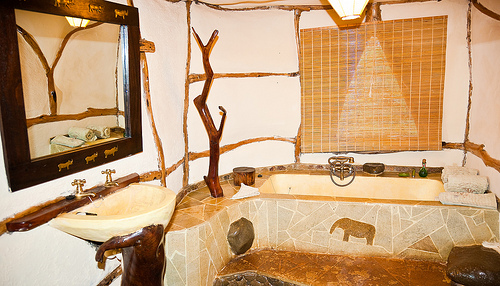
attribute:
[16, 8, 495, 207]
wall — here, white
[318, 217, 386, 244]
elephant — here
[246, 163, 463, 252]
bath tub — here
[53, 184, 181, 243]
sink — here, white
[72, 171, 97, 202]
faucet — gold, here, metallic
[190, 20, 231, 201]
tree branch — brown, decoration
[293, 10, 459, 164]
window covering — brown, wicker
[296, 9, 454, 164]
bamboo — hanging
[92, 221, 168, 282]
wood — here, brown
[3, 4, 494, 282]
picture — here